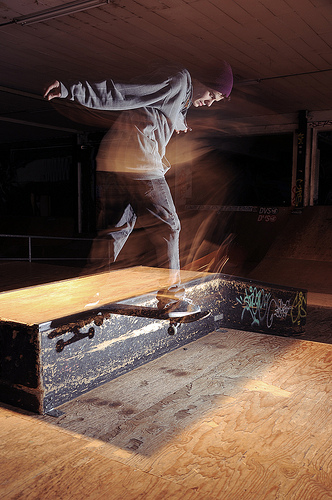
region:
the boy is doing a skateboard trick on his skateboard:
[45, 54, 220, 333]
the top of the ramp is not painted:
[1, 260, 217, 327]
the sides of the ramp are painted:
[6, 277, 305, 410]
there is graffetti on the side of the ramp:
[226, 283, 306, 332]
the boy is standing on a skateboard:
[88, 301, 208, 331]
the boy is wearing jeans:
[36, 54, 229, 319]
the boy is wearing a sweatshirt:
[47, 61, 235, 312]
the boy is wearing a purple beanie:
[53, 57, 236, 309]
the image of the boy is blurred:
[43, 60, 239, 319]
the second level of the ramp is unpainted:
[1, 324, 330, 498]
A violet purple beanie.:
[192, 51, 234, 97]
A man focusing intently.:
[187, 60, 234, 115]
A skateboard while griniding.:
[77, 298, 215, 339]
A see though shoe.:
[164, 296, 200, 317]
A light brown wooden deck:
[163, 374, 310, 493]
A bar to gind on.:
[35, 318, 88, 331]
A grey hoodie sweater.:
[56, 60, 190, 181]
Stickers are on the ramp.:
[259, 206, 279, 224]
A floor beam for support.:
[293, 123, 319, 208]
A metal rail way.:
[2, 234, 110, 265]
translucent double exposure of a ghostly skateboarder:
[42, 58, 232, 334]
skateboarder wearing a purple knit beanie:
[41, 54, 234, 333]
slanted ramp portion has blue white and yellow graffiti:
[219, 264, 306, 335]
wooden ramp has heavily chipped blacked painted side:
[0, 265, 308, 415]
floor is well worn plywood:
[0, 327, 331, 498]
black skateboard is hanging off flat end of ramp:
[0, 265, 218, 417]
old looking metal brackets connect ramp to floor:
[0, 265, 306, 421]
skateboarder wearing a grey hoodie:
[42, 57, 230, 316]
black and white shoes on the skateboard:
[74, 290, 210, 334]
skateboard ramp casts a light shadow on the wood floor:
[0, 265, 306, 458]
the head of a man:
[189, 55, 243, 110]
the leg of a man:
[122, 173, 186, 300]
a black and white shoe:
[156, 297, 206, 321]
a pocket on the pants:
[129, 173, 155, 197]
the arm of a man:
[60, 68, 184, 114]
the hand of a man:
[40, 74, 74, 106]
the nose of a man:
[203, 95, 216, 108]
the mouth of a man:
[196, 97, 204, 109]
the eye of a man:
[206, 89, 215, 100]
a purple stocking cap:
[182, 53, 238, 100]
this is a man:
[38, 39, 208, 249]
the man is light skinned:
[198, 87, 206, 94]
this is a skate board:
[121, 299, 191, 331]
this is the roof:
[248, 6, 291, 63]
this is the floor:
[188, 358, 324, 493]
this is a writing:
[248, 206, 278, 219]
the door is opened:
[314, 144, 331, 194]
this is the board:
[167, 376, 220, 448]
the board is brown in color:
[207, 399, 272, 447]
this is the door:
[310, 128, 326, 195]